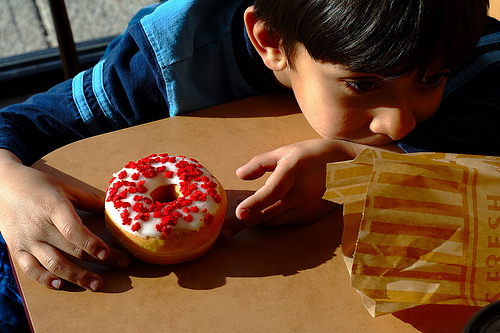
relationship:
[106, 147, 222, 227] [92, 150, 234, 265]
sprinkle on doughnut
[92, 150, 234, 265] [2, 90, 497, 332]
doughnut sitting on a table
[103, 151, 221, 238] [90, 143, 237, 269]
sprinkle on a doughnut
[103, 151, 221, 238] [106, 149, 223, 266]
sprinkle on a doughnut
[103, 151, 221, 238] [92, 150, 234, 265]
sprinkle on a doughnut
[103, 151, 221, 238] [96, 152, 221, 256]
sprinkle on a doughnut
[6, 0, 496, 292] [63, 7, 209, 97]
boy wearing a shirt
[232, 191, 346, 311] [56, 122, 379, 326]
shadow cast on table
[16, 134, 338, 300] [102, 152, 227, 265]
hands near donut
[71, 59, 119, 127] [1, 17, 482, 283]
stripes on a shirt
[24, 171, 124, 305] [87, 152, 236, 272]
hand touching donut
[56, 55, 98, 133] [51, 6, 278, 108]
stripes on shirt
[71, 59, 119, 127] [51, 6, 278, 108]
stripes on shirt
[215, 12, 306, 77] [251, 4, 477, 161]
ear on head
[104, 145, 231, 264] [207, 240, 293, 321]
donut on table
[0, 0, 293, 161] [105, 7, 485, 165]
shirt on boy